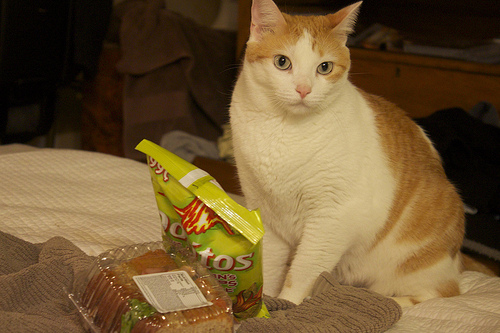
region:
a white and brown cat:
[219, 0, 468, 320]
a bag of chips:
[143, 139, 268, 323]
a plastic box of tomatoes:
[74, 241, 233, 331]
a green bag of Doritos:
[140, 139, 268, 319]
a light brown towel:
[3, 236, 390, 331]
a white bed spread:
[3, 133, 498, 325]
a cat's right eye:
[265, 49, 292, 74]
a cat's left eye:
[310, 57, 339, 77]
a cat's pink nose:
[292, 82, 312, 98]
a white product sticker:
[136, 266, 210, 316]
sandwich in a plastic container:
[98, 245, 220, 320]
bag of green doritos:
[172, 145, 272, 317]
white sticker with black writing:
[122, 247, 208, 329]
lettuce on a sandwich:
[122, 252, 221, 329]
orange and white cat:
[279, 100, 436, 302]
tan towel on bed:
[2, 200, 105, 306]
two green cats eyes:
[265, 53, 350, 78]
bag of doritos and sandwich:
[108, 150, 238, 327]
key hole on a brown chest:
[367, 59, 419, 98]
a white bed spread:
[37, 137, 129, 217]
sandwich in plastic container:
[73, 241, 234, 331]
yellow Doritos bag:
[140, 140, 270, 317]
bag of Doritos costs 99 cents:
[136, 137, 173, 184]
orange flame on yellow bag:
[154, 181, 236, 238]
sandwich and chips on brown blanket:
[0, 239, 402, 331]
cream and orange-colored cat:
[208, 2, 472, 311]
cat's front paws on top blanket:
[233, 240, 333, 311]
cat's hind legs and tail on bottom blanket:
[318, 245, 474, 306]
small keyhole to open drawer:
[388, 61, 406, 80]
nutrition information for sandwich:
[130, 266, 217, 314]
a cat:
[264, 111, 402, 331]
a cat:
[274, 97, 347, 262]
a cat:
[294, 158, 363, 285]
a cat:
[273, 182, 308, 228]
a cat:
[240, 97, 305, 286]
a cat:
[285, 198, 347, 299]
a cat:
[282, 182, 387, 319]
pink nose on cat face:
[236, 5, 372, 116]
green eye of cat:
[268, 50, 293, 71]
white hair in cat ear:
[253, 9, 296, 36]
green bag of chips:
[127, 132, 277, 319]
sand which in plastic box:
[65, 241, 245, 331]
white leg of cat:
[277, 212, 362, 307]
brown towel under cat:
[229, 285, 402, 332]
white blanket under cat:
[28, 143, 119, 200]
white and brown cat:
[218, 22, 489, 288]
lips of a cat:
[285, 94, 310, 111]